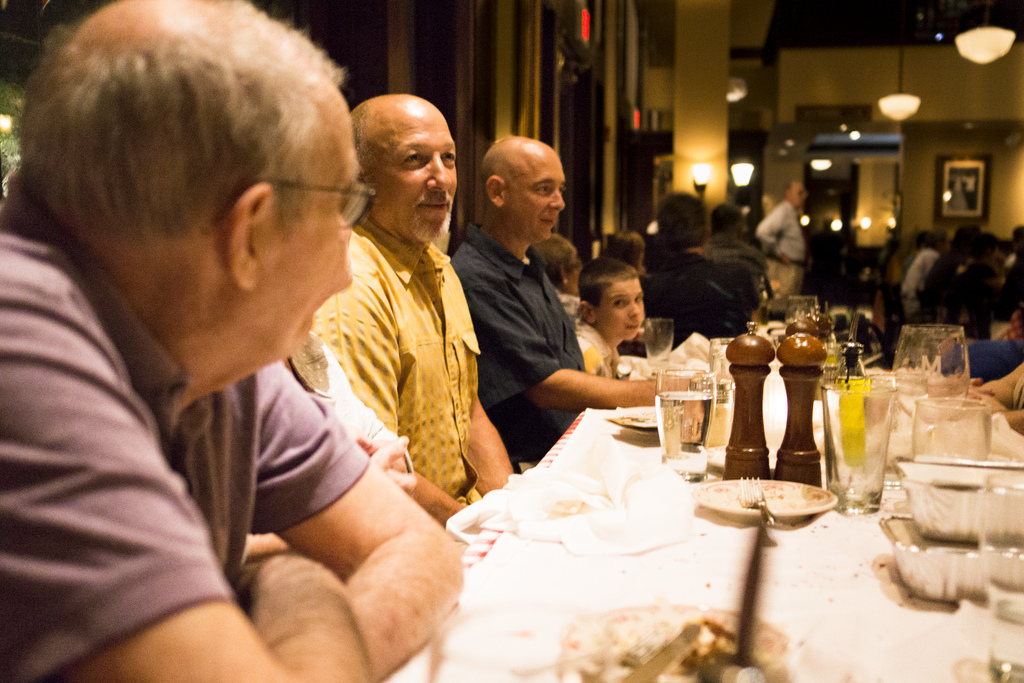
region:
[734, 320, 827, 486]
brown salt and pepper shakers on table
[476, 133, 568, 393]
man sitting at table with black shirt on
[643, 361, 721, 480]
Glass of water on the left side of salt and pepper shakers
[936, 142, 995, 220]
picture hanging on wall to the right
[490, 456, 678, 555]
White napkin sitting on table in front of man with yellow shirt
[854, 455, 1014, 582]
Ten pans sitting on table to the right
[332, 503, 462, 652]
Man with pinkish shirt elbows on table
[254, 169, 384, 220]
The glasses on the man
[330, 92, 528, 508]
The man wearing a yellow shirt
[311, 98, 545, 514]
The man with a bald head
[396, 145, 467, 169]
The eyes on the bald head man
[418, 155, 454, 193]
The nose of the yellow shirt man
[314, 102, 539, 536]
The man with a beard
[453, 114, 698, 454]
The man wearing a blue shirt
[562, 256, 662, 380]
The young boy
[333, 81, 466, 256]
A man has a bald head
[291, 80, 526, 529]
A man wearing a yellow shirt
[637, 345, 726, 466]
A glass of water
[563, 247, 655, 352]
Boy has brown hair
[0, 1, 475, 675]
A man has his elbows on the table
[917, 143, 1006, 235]
Framed painting on the wall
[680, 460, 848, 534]
A small white plate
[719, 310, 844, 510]
these are salt and pepper shakers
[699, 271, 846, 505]
wooden salt and pepper shakers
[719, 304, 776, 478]
this is a pepper grinder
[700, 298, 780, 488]
a wooden pepper grinder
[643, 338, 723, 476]
this is a glass of water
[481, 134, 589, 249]
man with bald head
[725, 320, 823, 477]
wood salt and pepper shakers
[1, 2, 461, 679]
man with crossed arms on table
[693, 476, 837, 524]
fork on top of round plate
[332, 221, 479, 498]
yellow shirt with front pocket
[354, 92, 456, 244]
man with gray goatee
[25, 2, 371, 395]
glasses on man's face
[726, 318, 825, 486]
wooden salt and pepper shakers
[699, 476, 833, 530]
fork on a plate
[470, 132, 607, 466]
man wearing a black shirt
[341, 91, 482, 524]
man wearing a yellow shirt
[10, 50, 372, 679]
man wearing a purple shirt